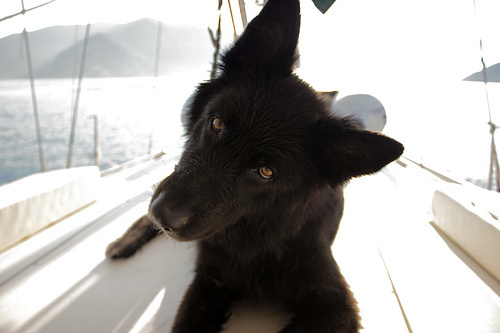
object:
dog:
[101, 0, 365, 333]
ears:
[325, 129, 404, 184]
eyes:
[252, 163, 287, 186]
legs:
[172, 275, 240, 331]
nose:
[149, 185, 197, 230]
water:
[0, 64, 500, 186]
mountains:
[30, 31, 151, 79]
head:
[145, 0, 411, 243]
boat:
[0, 138, 500, 333]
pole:
[64, 24, 94, 171]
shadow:
[2, 185, 154, 292]